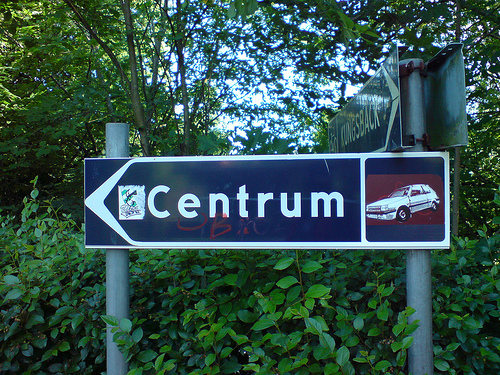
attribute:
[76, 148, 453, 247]
sign — blue, white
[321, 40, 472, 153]
sign — blue, white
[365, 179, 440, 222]
car — white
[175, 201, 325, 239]
graffiti — red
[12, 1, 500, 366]
trees — lush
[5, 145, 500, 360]
bushes — very thick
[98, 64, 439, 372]
posts — metal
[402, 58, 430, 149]
bolts — rusted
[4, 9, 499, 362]
picture — outdoors